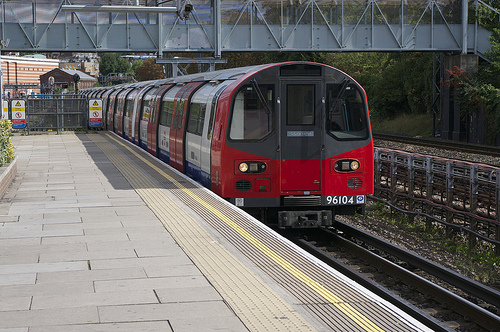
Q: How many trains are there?
A: One.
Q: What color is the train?
A: Red.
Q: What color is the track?
A: Black.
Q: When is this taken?
A: During the day.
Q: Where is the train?
A: On the tracks.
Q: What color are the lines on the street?
A: Yellow.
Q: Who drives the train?
A: An engineer.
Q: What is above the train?
A: A bridge.